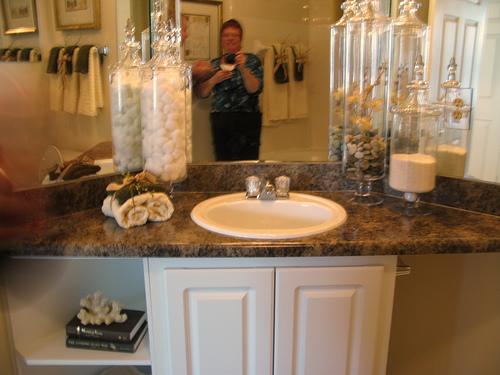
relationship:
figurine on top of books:
[75, 289, 129, 326] [64, 306, 146, 351]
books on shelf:
[64, 306, 146, 351] [13, 327, 149, 366]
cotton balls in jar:
[138, 69, 192, 180] [140, 3, 193, 181]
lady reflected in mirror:
[193, 18, 264, 160] [5, 4, 495, 190]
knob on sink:
[273, 175, 292, 198] [189, 173, 348, 239]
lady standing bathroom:
[193, 18, 264, 160] [3, 9, 483, 372]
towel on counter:
[101, 171, 171, 229] [30, 183, 228, 294]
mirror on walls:
[0, 0, 500, 190] [195, 3, 345, 133]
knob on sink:
[245, 176, 261, 197] [179, 164, 347, 277]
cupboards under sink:
[163, 237, 383, 371] [166, 163, 329, 250]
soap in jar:
[384, 155, 430, 188] [376, 63, 465, 245]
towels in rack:
[44, 44, 104, 116] [49, 36, 121, 63]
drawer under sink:
[260, 261, 404, 370] [181, 164, 359, 255]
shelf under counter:
[32, 268, 164, 370] [198, 159, 380, 246]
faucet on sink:
[249, 171, 317, 203] [197, 197, 344, 240]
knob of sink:
[245, 176, 256, 198] [187, 190, 346, 240]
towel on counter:
[101, 171, 171, 226] [5, 190, 495, 254]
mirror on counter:
[5, 4, 495, 190] [0, 188, 496, 249]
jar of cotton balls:
[138, 20, 188, 181] [158, 89, 181, 169]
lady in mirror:
[193, 18, 264, 160] [5, 4, 495, 190]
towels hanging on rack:
[44, 52, 104, 117] [98, 48, 109, 54]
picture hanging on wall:
[5, 3, 34, 33] [0, 2, 130, 186]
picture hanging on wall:
[50, 4, 99, 30] [0, 2, 130, 186]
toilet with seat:
[35, 143, 80, 180] [37, 146, 58, 180]